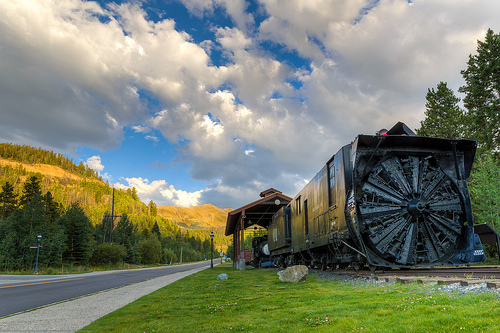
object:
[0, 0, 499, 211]
sky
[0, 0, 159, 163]
clouds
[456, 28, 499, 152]
leaves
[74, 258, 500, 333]
grass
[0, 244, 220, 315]
road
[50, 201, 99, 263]
trees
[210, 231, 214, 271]
posts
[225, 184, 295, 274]
station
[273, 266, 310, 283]
rock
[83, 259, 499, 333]
grass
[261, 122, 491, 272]
train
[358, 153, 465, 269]
fan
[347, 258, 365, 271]
tracks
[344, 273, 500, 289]
ties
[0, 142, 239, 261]
hills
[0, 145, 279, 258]
sunlight